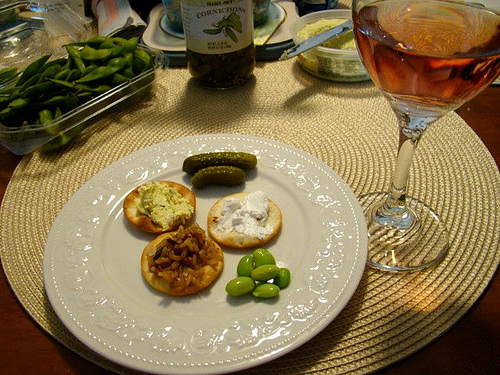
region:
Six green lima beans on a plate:
[224, 249, 290, 299]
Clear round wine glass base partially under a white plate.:
[355, 192, 447, 274]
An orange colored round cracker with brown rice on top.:
[140, 232, 223, 295]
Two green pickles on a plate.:
[180, 149, 257, 188]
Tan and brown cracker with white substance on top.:
[205, 190, 282, 250]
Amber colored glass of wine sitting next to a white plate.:
[352, 0, 499, 275]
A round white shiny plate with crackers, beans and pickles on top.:
[42, 132, 367, 374]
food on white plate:
[36, 129, 373, 374]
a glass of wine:
[339, 0, 494, 277]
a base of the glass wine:
[349, 186, 453, 277]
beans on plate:
[221, 245, 294, 307]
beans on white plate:
[223, 245, 293, 304]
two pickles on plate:
[176, 148, 263, 192]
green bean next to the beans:
[247, 263, 281, 283]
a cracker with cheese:
[205, 188, 286, 250]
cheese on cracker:
[218, 188, 270, 230]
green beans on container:
[1, 2, 171, 159]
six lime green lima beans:
[224, 247, 292, 302]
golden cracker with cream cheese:
[209, 188, 282, 248]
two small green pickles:
[180, 145, 260, 191]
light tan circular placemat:
[0, 46, 497, 372]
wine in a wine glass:
[341, 0, 498, 277]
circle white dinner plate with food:
[45, 132, 368, 372]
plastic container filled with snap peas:
[0, 1, 171, 157]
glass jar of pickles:
[179, 0, 257, 90]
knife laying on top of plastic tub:
[279, 8, 371, 84]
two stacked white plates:
[137, 3, 302, 63]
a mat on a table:
[12, 252, 36, 336]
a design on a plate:
[321, 224, 361, 295]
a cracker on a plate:
[216, 206, 280, 238]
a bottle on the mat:
[179, 27, 271, 103]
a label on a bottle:
[190, 7, 262, 59]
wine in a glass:
[352, 19, 490, 156]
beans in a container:
[23, 56, 98, 154]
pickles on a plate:
[176, 141, 264, 192]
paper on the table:
[88, 5, 159, 37]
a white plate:
[40, 129, 372, 374]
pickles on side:
[180, 146, 258, 186]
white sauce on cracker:
[216, 187, 268, 239]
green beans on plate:
[225, 246, 290, 303]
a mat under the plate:
[0, 37, 498, 374]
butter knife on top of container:
[274, 14, 361, 59]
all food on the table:
[3, 6, 498, 373]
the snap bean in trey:
[1, 11, 159, 161]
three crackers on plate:
[118, 177, 281, 299]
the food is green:
[223, 231, 298, 311]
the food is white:
[220, 184, 295, 251]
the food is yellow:
[132, 183, 179, 225]